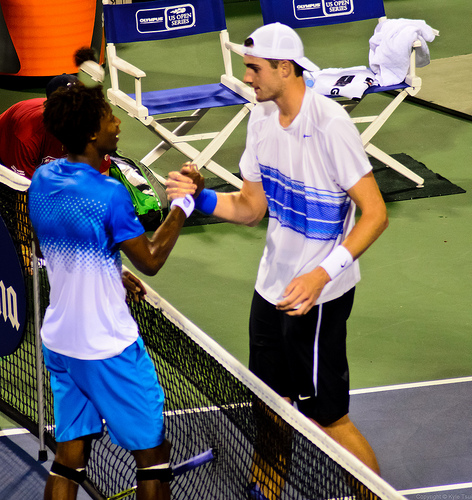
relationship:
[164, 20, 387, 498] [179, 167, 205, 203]
man has hand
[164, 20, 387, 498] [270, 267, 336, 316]
man has hand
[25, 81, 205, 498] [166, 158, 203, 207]
man has hand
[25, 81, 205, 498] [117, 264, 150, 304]
man has hand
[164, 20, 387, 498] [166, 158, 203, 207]
man shaking hand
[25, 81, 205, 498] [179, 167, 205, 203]
man shaking hand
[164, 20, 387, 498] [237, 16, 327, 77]
man in cap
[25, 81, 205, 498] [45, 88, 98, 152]
man has black hair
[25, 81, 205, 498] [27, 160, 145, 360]
man in shirt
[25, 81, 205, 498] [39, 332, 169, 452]
man in blue shorts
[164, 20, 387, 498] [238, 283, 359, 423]
man wearing shorts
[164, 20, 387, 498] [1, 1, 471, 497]
man on court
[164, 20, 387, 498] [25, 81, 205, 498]
man holding hands with man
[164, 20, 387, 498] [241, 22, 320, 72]
man wearing backwards cap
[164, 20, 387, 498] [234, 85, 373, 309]
man wearing shirt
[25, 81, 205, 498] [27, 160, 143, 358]
man wearing shirt